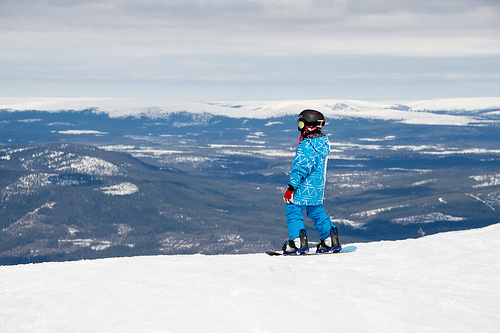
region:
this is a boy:
[273, 90, 340, 250]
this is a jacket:
[303, 155, 333, 200]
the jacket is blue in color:
[305, 162, 325, 197]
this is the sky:
[175, 26, 344, 97]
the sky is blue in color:
[253, 55, 317, 87]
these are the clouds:
[218, 0, 354, 25]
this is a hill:
[44, 137, 136, 237]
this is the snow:
[355, 102, 397, 120]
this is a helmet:
[294, 102, 326, 127]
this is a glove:
[278, 188, 293, 203]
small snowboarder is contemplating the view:
[266, 109, 356, 256]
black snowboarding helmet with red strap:
[297, 108, 326, 142]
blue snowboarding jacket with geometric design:
[287, 135, 328, 206]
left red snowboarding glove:
[282, 184, 294, 202]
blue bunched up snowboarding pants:
[285, 201, 334, 238]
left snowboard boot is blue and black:
[284, 228, 308, 255]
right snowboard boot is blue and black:
[315, 227, 340, 253]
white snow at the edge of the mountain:
[0, 223, 499, 330]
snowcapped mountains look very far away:
[0, 98, 499, 265]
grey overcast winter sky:
[0, 0, 498, 100]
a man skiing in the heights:
[251, 109, 364, 259]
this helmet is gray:
[300, 110, 324, 120]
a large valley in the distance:
[5, 132, 257, 249]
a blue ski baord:
[260, 237, 354, 254]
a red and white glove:
[282, 187, 295, 204]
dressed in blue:
[283, 138, 339, 240]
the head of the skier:
[297, 111, 327, 133]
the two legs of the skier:
[284, 205, 336, 242]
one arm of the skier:
[288, 145, 312, 188]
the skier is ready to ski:
[253, 97, 372, 299]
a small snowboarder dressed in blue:
[258, 105, 358, 265]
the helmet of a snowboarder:
[295, 103, 333, 123]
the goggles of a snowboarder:
[298, 118, 326, 133]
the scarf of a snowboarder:
[298, 126, 324, 142]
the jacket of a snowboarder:
[283, 137, 335, 205]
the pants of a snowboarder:
[280, 200, 335, 240]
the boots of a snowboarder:
[285, 233, 342, 250]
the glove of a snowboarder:
[279, 182, 299, 205]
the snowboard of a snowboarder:
[266, 244, 357, 257]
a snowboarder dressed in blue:
[266, 103, 353, 275]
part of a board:
[301, 227, 331, 265]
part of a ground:
[251, 246, 286, 291]